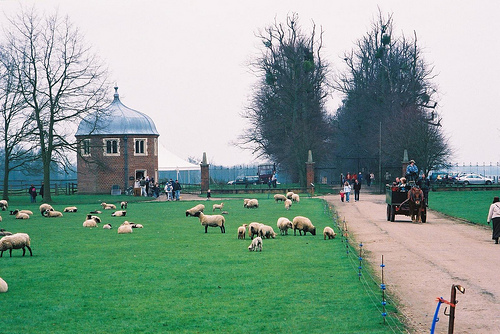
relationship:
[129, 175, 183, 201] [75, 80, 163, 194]
people standing outside a building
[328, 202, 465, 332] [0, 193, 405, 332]
fence on side of field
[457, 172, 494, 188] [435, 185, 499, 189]
car on road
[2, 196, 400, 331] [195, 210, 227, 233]
grass with sheep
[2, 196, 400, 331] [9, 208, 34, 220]
grass with sheep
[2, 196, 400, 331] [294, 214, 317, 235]
grass with sheep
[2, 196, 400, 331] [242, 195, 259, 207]
grass with sheep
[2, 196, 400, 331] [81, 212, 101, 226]
grass with sheep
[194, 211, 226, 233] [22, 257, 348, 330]
sheep walking on green grass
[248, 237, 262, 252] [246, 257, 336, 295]
sheep walking on green grass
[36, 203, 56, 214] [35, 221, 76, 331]
sheep walking on green grass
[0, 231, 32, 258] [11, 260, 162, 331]
sheep walking in green grass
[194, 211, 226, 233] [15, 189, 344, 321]
sheep on grass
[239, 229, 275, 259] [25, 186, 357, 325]
sheep on grass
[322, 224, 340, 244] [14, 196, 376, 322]
sheep on grass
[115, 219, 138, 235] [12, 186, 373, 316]
sheep on grass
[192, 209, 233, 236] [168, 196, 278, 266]
sheep on grass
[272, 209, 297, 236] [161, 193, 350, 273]
sheep on grass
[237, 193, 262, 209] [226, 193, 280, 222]
sheep on grass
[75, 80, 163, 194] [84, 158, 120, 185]
building has wall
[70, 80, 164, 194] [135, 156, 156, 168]
building has wall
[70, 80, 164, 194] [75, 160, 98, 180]
building has wall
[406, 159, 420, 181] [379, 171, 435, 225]
man pulls wagon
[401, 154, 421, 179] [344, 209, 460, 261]
man on road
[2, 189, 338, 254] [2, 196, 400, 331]
sheep on grass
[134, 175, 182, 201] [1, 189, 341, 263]
people watch animals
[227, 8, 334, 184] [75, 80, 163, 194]
tree standing next to building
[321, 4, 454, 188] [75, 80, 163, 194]
tree standing next to building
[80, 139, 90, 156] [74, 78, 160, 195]
window adorning building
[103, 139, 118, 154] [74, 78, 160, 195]
window adorning building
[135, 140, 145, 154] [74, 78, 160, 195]
window adorning building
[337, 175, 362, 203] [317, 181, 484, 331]
family walking down road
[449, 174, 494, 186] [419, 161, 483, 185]
car parked in parking lot